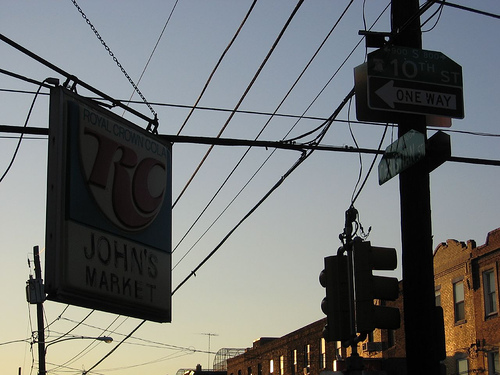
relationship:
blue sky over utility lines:
[8, 5, 492, 267] [0, 124, 500, 169]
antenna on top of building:
[159, 314, 257, 362] [180, 365, 232, 370]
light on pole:
[43, 335, 113, 356] [39, 330, 125, 359]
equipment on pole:
[25, 274, 46, 305] [26, 243, 52, 373]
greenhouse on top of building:
[212, 347, 243, 365] [122, 187, 493, 372]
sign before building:
[46, 80, 179, 326] [175, 225, 500, 374]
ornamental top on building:
[431, 235, 477, 265] [430, 237, 477, 374]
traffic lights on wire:
[315, 237, 397, 343] [338, 114, 387, 239]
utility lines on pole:
[0, 0, 446, 373] [392, 0, 448, 372]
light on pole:
[46, 335, 113, 347] [32, 245, 48, 375]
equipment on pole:
[26, 277, 47, 303] [32, 245, 48, 375]